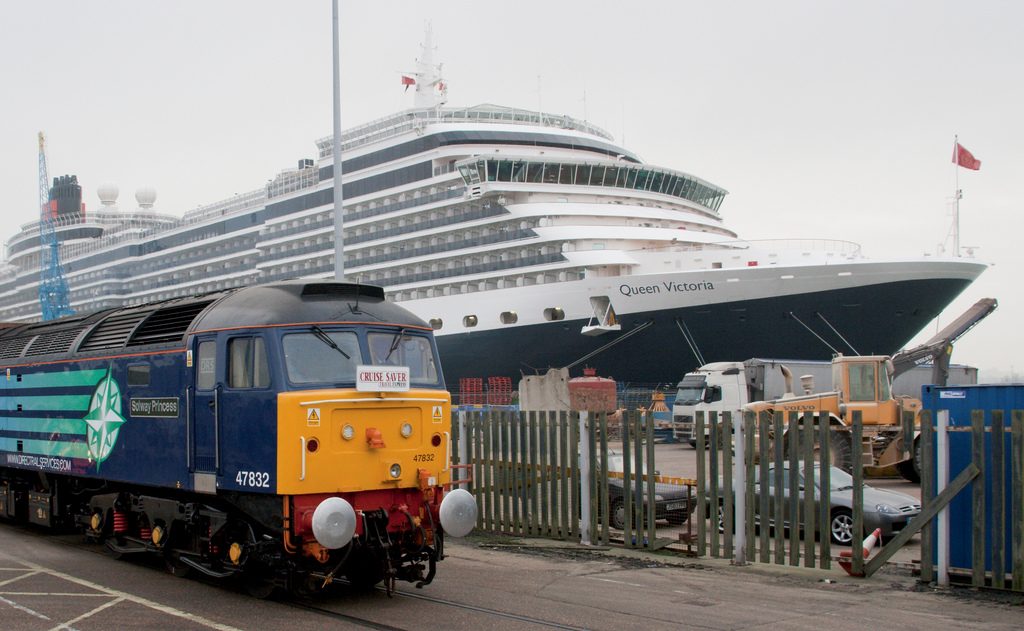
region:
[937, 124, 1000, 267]
flag on a pole on ship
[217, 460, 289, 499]
number on a train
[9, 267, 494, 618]
train near a port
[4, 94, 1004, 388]
cruise ship docked at a port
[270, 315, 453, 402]
front windows of a train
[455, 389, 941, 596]
fence on the side of a train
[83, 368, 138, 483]
design on side of train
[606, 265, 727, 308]
name of a ship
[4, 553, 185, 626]
white lines painted on the road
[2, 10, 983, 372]
Large passenger cruise ship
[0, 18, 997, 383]
The Queen Victoria cruise ship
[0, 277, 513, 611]
Yellow and blue passenger train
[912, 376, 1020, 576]
Large blue waste bin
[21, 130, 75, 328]
Blue crane behind the train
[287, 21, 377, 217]
a clear view of pole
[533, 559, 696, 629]
a clear view of road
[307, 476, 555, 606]
front of the train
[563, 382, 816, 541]
a fence near train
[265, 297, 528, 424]
glass of the train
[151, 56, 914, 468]
a big steamer in water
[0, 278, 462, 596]
A locomotive opposite the harbour.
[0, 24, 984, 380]
The high storied vessel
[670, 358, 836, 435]
The white truck next to the ship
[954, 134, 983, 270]
The red flag on the cruise ship.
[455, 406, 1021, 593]
A bars built fence.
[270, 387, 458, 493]
The train's yellow painted front.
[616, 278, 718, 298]
The cruise ship name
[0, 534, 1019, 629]
A flat ground with tracks.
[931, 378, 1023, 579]
The blue container on the right.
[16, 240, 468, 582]
multicolored train near boat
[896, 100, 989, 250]
red flag on front of ship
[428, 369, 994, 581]
broken wooden fence near train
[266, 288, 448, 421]
windshield of front of train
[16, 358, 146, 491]
aqua blue logo on train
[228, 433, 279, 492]
numbers written in white on train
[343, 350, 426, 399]
white and red sign on front of train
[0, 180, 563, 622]
a train on front a ship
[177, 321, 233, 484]
the door is blue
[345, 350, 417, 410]
a sign on front a train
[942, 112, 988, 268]
the red flag on front a ship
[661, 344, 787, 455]
the truck is white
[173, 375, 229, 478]
the handles of a door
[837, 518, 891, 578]
a cone white and orange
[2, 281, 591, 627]
the train on the track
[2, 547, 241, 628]
the lines are white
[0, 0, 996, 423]
the boat is massive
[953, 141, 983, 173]
the flag is red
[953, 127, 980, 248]
the flag on the pole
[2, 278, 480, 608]
the train is very colorful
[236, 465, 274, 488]
the numbers are white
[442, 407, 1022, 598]
the fence is green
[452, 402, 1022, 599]
the fence is green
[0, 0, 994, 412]
the massive boat is called queen victoria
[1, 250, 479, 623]
navy blue train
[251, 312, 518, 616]
orange and red train front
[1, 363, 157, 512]
green side of train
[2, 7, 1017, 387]
cloudy gray sky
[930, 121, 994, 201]
red flag on front of boat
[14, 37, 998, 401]
white and blue cruise ship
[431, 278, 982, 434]
navy blue bottom of ship